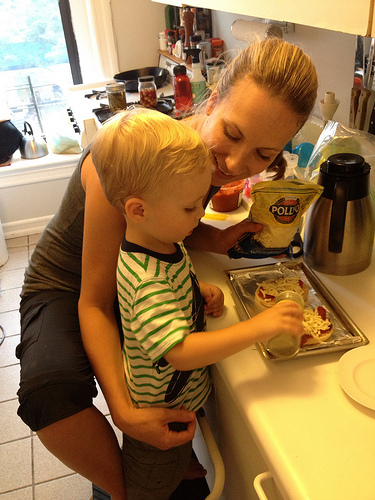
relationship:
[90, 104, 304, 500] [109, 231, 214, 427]
boy in shirt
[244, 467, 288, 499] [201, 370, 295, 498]
handle on a cabinet drawer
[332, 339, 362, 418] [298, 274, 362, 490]
plate on a counter top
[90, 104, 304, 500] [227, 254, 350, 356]
boy helping make food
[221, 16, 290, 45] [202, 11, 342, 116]
rack on wall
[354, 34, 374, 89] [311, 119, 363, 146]
knives near a counter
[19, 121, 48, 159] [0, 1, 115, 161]
coffee pot by a window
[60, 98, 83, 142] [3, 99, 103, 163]
control knobs on a stove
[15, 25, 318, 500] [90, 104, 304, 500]
mom holding boy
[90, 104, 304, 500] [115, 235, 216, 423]
boy wearing shirt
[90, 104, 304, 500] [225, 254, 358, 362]
boy making a pizza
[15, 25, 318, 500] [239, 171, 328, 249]
mom holding bag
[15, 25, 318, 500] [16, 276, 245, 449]
mom wearing shorts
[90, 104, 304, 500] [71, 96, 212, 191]
boy has hair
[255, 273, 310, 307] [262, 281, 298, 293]
pizzas with cheese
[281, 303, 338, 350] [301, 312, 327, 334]
pizza with cheese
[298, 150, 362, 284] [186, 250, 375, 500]
coffee pot on a counter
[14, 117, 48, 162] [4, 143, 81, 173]
coffee pot on a counter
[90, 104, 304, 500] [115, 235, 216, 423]
boy with a shirt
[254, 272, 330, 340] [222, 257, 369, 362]
pizzas on baking sheet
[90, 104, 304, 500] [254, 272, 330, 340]
boy making pizzas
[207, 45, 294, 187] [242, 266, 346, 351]
mom helping cook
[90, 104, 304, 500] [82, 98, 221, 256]
boy with hair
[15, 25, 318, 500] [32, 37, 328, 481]
mom with hair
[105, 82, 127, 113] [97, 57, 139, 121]
food of food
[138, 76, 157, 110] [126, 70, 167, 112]
food of food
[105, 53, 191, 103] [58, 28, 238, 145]
pan on a stove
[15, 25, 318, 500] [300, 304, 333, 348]
mom making pizza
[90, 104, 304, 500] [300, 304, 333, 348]
boy making pizza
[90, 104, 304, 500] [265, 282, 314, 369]
boy pouring cheese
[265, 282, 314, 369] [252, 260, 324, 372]
cheese on pizzas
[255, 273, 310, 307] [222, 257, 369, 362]
pizzas on a baking sheet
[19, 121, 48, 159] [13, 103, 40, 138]
coffee pot with a handle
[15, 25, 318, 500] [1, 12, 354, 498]
mom in a kitchen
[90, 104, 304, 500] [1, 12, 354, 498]
boy in a kitchen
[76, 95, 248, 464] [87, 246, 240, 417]
boy wearing a shirt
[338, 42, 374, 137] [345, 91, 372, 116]
knives with handles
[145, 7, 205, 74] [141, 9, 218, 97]
spices on shelf